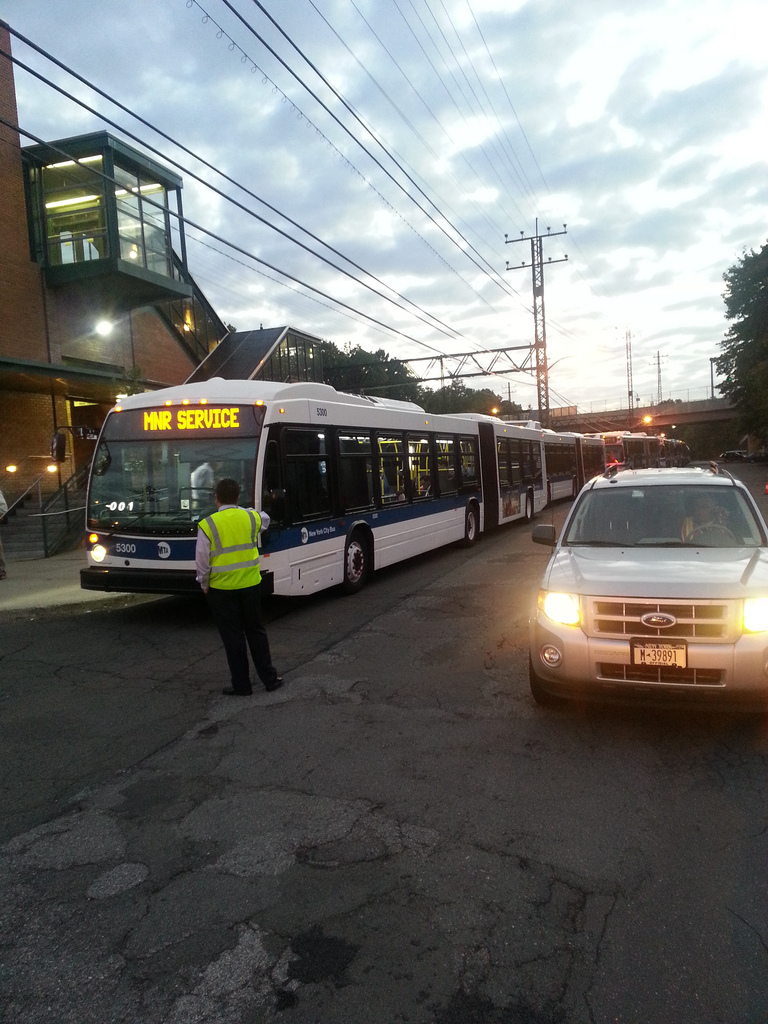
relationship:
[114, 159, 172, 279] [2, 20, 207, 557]
window adorning building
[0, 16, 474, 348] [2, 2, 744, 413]
wire hanging in air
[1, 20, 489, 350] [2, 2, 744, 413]
wire hanging in air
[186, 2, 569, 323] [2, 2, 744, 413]
wire hanging in air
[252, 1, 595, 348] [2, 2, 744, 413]
wire hanging in air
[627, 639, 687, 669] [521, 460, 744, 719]
license plate of gray car